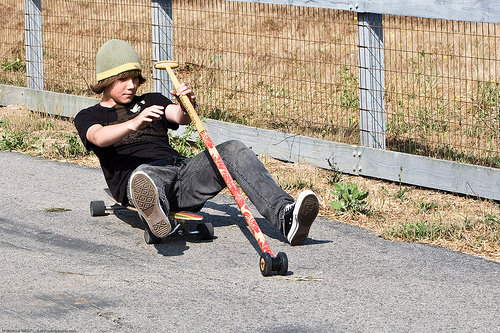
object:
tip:
[169, 207, 204, 221]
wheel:
[89, 200, 107, 217]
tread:
[132, 175, 171, 238]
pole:
[153, 59, 284, 257]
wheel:
[258, 251, 278, 277]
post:
[356, 12, 390, 152]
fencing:
[1, 1, 500, 203]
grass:
[1, 0, 500, 267]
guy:
[73, 35, 321, 248]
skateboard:
[89, 185, 216, 245]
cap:
[94, 38, 143, 82]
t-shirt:
[73, 91, 186, 208]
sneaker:
[278, 188, 322, 248]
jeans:
[126, 140, 298, 239]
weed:
[327, 179, 371, 216]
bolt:
[356, 151, 362, 159]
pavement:
[0, 151, 500, 333]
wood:
[1, 82, 500, 204]